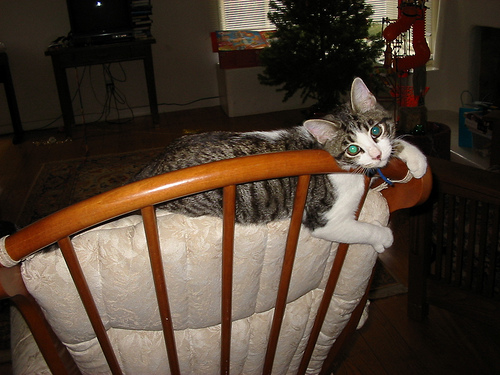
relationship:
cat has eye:
[134, 74, 425, 250] [344, 142, 362, 156]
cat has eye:
[134, 74, 425, 250] [371, 123, 382, 136]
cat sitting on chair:
[134, 74, 425, 250] [6, 141, 428, 374]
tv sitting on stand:
[67, 1, 132, 39] [44, 35, 167, 121]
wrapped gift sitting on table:
[211, 28, 272, 52] [213, 49, 325, 116]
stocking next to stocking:
[382, 1, 415, 42] [390, 9, 438, 65]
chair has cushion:
[6, 141, 428, 374] [0, 186, 388, 374]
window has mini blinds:
[219, 0, 441, 75] [220, 1, 403, 57]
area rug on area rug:
[15, 133, 201, 245] [0, 110, 499, 332]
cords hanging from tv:
[44, 60, 217, 127] [67, 1, 132, 39]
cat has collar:
[134, 74, 425, 250] [362, 164, 395, 186]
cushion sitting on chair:
[0, 186, 388, 374] [6, 141, 428, 374]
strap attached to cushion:
[1, 233, 23, 270] [0, 186, 388, 374]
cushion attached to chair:
[0, 186, 388, 374] [6, 141, 428, 374]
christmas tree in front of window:
[259, 1, 390, 109] [219, 0, 441, 75]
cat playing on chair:
[134, 74, 425, 250] [6, 141, 428, 374]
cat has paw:
[134, 74, 425, 250] [398, 140, 429, 180]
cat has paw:
[134, 74, 425, 250] [369, 220, 391, 253]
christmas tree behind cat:
[259, 1, 390, 109] [134, 74, 425, 250]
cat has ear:
[134, 74, 425, 250] [302, 118, 339, 143]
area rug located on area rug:
[15, 133, 201, 245] [0, 110, 499, 332]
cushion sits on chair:
[0, 186, 388, 374] [6, 141, 428, 374]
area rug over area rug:
[15, 133, 201, 245] [0, 110, 499, 332]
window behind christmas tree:
[219, 0, 441, 75] [259, 1, 390, 109]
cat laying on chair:
[134, 74, 425, 250] [6, 141, 428, 374]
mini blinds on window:
[220, 1, 403, 57] [219, 0, 441, 75]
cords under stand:
[44, 60, 217, 127] [44, 35, 167, 121]